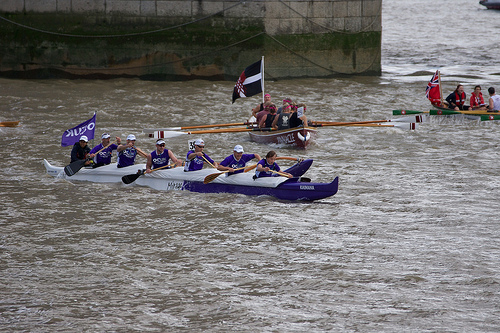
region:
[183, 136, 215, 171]
male rower is rowing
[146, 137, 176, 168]
male rower is rowing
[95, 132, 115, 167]
male rower is rowing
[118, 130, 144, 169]
male rower is rowing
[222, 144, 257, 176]
male rower is rowing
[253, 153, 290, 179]
female rower is rowing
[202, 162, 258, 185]
long wooden skinny ore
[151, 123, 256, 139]
long wooden skinny ore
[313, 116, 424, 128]
long wooden skinny ore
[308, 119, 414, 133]
long wooden skinny ore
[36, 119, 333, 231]
kayaking team with the color of purple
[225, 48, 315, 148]
Another kayaking team in the water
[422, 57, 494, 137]
Third Kayaking team at rest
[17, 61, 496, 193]
three kayaking teams in the water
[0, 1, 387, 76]
Bridge out in the water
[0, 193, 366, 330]
river water rippling down stream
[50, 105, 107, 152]
Purple and white flag of the kayaking team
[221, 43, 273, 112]
Red , black and white flag of second kayaking team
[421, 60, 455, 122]
red white and blue flag of third kayaking team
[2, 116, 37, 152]
Small bit of a paddle from another team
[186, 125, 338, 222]
FRONT OF THE BOAT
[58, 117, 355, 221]
PEOPLE ROWING THE BOAT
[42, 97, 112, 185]
TEAM'S PURPLE FLAG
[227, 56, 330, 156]
ROWING A MAROON BOAT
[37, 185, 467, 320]
CHOPPY WATER TO ROW IN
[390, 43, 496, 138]
TEAM ROWING A GREEN BOAT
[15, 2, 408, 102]
BOTTOM OF A BRIDGE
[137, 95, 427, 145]
LONG OARS FOR ROWING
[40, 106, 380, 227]
PURPLE AND WHITE BOAT IN THE WATER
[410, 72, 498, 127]
PEOPLE WEARING LIFE VESTS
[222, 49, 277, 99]
red white and black flag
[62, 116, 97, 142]
Purple and white flag on kayak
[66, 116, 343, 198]
leading kayak team in the water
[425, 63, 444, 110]
red white and blue flag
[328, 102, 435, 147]
kayak paddles in the water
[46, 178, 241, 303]
Ocean water to kayak in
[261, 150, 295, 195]
first kayaker in the boat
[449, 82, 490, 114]
Two People with Life jackets on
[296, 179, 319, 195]
name on the front of the boat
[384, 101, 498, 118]
green kayak in the water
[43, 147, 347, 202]
The kayak is blue and white.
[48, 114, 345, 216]
People are sitting in the kayak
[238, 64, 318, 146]
The flag is behind the people on the boat.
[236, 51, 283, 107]
The flag is red, white and black.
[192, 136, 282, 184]
The people have on purple shirts.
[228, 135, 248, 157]
A man has on a white cap.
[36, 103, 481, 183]
Kayaks in the water.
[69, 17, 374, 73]
A wall of cement is behind the people on the kayaks.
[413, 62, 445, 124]
The flag is red, white and blue.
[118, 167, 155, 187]
A man has a oar in his hands.